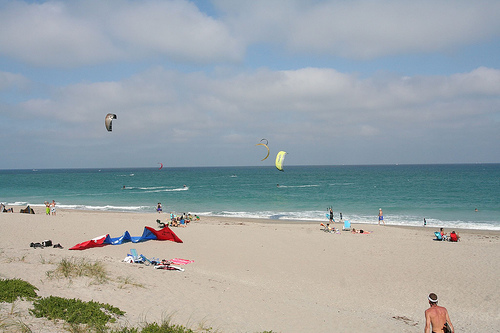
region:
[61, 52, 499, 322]
the scene is at a beach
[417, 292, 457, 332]
the man is half dressed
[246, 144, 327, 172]
the kite are suspended in the atmosphere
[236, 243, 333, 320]
the foor is sandy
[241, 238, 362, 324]
the floor is light brwon in color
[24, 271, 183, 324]
the floor is covered with green plants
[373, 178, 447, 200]
the water is blue in color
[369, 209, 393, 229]
a man walking to the sea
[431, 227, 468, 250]
two people seated and watching the sea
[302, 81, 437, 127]
the sky is covered with white clouds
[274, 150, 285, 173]
a yellow kite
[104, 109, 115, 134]
a white kite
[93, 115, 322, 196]
wind kites in the air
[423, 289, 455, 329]
a person walking to the beach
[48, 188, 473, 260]
people on the beach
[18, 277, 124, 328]
grass in the sand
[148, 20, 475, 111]
clouds in the sky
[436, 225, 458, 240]
two people sitting on the beach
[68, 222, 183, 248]
a red and blue kite on the beach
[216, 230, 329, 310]
sand on the beach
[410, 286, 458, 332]
man who is not wearing a shirt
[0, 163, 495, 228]
light blue body of water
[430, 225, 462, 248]
people sitting on the beach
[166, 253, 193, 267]
pink towel laying on the sand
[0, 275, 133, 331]
greenery growing in the sand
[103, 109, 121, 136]
kite in the sky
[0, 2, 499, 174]
thick white clouds in the sky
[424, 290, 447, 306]
white band around the head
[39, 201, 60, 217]
two people standing on the sand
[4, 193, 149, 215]
small waves rolling into shore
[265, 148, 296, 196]
yellow kite in sky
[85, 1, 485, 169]
blue and white sky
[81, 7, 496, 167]
puffy clouds in sky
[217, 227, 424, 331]
sand is light brown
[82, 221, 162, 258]
red and blue tents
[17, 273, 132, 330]
green vegetation on sand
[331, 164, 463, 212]
water is dark blue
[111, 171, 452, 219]
few white waves on water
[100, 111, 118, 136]
black kite in sky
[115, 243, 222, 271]
blue and red chairs on sand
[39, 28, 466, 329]
people are in a beach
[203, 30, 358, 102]
the sky is cloudt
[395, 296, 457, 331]
the man is shirtless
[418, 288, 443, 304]
a white band is on the head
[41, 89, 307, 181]
surfs are on the air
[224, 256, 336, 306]
the sand is brown in colour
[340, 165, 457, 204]
the water is bluish in colour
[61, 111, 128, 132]
the surfs are curved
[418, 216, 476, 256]
people are seated down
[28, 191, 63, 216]
people are standing talking